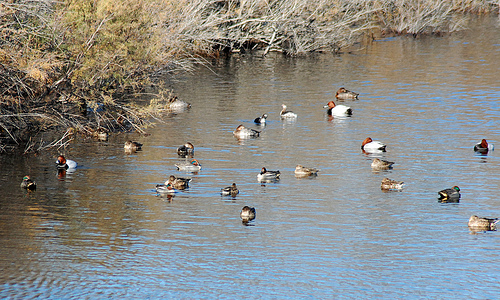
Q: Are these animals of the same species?
A: Yes, all the animals are ducks.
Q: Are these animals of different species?
A: No, all the animals are ducks.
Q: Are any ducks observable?
A: Yes, there is a duck.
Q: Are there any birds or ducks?
A: Yes, there is a duck.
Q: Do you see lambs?
A: No, there are no lambs.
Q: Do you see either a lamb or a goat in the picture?
A: No, there are no lambs or goats.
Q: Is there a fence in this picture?
A: No, there are no fences.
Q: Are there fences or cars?
A: No, there are no fences or cars.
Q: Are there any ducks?
A: Yes, there is a duck.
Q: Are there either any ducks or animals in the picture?
A: Yes, there is a duck.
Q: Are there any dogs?
A: No, there are no dogs.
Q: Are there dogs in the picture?
A: No, there are no dogs.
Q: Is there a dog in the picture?
A: No, there are no dogs.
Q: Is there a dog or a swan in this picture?
A: No, there are no dogs or swans.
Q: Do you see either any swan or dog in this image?
A: No, there are no dogs or swans.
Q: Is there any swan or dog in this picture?
A: No, there are no dogs or swans.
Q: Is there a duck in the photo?
A: Yes, there is a duck.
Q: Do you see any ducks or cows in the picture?
A: Yes, there is a duck.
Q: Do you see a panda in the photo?
A: No, there are no pandas.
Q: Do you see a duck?
A: Yes, there is a duck.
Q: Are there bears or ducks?
A: Yes, there is a duck.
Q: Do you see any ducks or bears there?
A: Yes, there is a duck.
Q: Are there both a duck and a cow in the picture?
A: No, there is a duck but no cows.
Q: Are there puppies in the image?
A: No, there are no puppies.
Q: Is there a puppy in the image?
A: No, there are no puppies.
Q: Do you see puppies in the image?
A: No, there are no puppies.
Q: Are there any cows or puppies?
A: No, there are no puppies or cows.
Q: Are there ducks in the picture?
A: Yes, there is a duck.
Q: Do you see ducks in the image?
A: Yes, there is a duck.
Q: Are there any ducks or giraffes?
A: Yes, there is a duck.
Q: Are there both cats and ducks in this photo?
A: No, there is a duck but no cats.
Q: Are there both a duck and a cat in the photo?
A: No, there is a duck but no cats.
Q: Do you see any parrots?
A: No, there are no parrots.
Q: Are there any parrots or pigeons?
A: No, there are no parrots or pigeons.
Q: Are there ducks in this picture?
A: Yes, there is a duck.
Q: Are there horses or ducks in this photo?
A: Yes, there is a duck.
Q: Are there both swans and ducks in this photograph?
A: No, there is a duck but no swans.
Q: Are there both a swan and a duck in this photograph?
A: No, there is a duck but no swans.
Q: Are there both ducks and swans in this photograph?
A: No, there is a duck but no swans.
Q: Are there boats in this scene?
A: No, there are no boats.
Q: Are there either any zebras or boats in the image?
A: No, there are no boats or zebras.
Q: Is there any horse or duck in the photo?
A: Yes, there is a duck.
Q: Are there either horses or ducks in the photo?
A: Yes, there is a duck.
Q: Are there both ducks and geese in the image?
A: No, there is a duck but no geese.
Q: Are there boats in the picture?
A: No, there are no boats.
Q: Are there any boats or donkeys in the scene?
A: No, there are no boats or donkeys.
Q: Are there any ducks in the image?
A: Yes, there are ducks.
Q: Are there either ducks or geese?
A: Yes, there are ducks.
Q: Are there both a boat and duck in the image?
A: No, there are ducks but no boats.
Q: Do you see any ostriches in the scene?
A: No, there are no ostriches.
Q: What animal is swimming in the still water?
A: The ducks are swimming in the water.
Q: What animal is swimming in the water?
A: The ducks are swimming in the water.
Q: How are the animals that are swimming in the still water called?
A: The animals are ducks.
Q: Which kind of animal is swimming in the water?
A: The animals are ducks.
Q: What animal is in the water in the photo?
A: The ducks are in the water.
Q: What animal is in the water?
A: The ducks are in the water.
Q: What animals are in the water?
A: The animals are ducks.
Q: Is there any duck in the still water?
A: Yes, there are ducks in the water.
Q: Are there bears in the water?
A: No, there are ducks in the water.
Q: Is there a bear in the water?
A: No, there are ducks in the water.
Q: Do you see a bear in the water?
A: No, there are ducks in the water.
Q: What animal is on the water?
A: The ducks are on the water.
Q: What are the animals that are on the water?
A: The animals are ducks.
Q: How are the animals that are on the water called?
A: The animals are ducks.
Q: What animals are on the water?
A: The animals are ducks.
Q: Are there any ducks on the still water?
A: Yes, there are ducks on the water.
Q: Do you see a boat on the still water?
A: No, there are ducks on the water.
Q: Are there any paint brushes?
A: No, there are no paint brushes.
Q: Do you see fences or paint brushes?
A: No, there are no paint brushes or fences.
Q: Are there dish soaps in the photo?
A: No, there are no dish soaps.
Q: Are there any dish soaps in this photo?
A: No, there are no dish soaps.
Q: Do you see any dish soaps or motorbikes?
A: No, there are no dish soaps or motorbikes.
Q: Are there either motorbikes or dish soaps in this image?
A: No, there are no dish soaps or motorbikes.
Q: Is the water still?
A: Yes, the water is still.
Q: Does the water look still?
A: Yes, the water is still.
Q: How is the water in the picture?
A: The water is still.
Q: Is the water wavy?
A: No, the water is still.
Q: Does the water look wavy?
A: No, the water is still.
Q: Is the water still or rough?
A: The water is still.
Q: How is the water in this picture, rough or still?
A: The water is still.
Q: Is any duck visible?
A: Yes, there is a duck.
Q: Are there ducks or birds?
A: Yes, there is a duck.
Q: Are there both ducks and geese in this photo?
A: No, there is a duck but no geese.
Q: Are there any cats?
A: No, there are no cats.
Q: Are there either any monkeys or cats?
A: No, there are no cats or monkeys.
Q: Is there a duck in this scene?
A: Yes, there is a duck.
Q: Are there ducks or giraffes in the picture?
A: Yes, there is a duck.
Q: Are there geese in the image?
A: No, there are no geese.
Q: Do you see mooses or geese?
A: No, there are no geese or mooses.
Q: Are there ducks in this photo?
A: Yes, there is a duck.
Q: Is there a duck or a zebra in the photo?
A: Yes, there is a duck.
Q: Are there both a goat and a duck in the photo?
A: No, there is a duck but no goats.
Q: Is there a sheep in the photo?
A: No, there is no sheep.